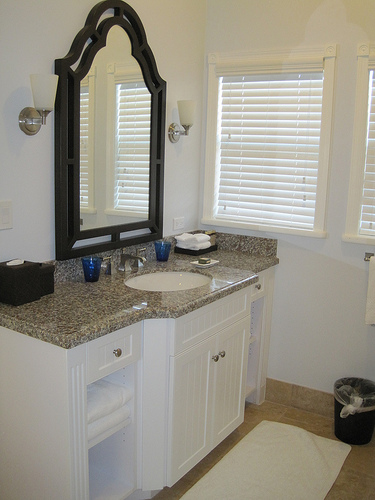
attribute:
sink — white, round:
[124, 266, 210, 291]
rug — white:
[172, 407, 352, 495]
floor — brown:
[148, 392, 374, 498]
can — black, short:
[328, 380, 364, 431]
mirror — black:
[43, 19, 200, 233]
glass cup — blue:
[84, 255, 102, 280]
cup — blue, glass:
[74, 255, 100, 282]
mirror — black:
[53, 1, 165, 260]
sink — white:
[123, 267, 212, 292]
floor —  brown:
[167, 380, 373, 497]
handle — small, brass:
[97, 341, 152, 379]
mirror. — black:
[52, 1, 168, 262]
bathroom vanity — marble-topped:
[85, 245, 260, 336]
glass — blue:
[81, 256, 99, 281]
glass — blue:
[152, 236, 172, 261]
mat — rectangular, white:
[153, 416, 360, 498]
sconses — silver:
[21, 107, 50, 139]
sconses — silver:
[169, 122, 189, 145]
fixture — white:
[29, 71, 61, 107]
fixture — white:
[177, 95, 194, 125]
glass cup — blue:
[75, 251, 113, 283]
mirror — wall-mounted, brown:
[80, 27, 151, 227]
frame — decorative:
[51, 1, 171, 264]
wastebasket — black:
[329, 374, 374, 449]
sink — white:
[116, 255, 221, 323]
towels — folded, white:
[174, 228, 210, 252]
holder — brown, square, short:
[0, 258, 61, 305]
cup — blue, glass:
[155, 238, 171, 259]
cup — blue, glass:
[75, 249, 108, 292]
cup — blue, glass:
[150, 236, 173, 264]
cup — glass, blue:
[79, 252, 105, 282]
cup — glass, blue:
[150, 239, 171, 260]